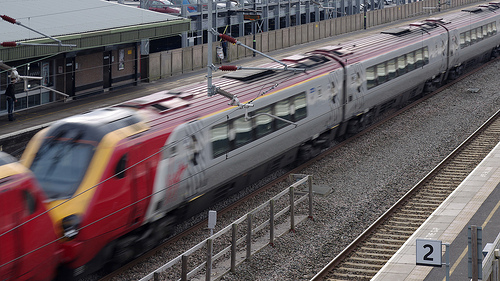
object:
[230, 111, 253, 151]
window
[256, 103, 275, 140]
window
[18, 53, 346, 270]
train section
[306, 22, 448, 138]
train section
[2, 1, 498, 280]
train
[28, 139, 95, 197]
window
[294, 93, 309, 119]
window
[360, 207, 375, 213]
rocks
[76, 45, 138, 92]
wall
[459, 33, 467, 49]
windows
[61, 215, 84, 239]
headlight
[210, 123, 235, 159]
windows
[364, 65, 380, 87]
windows